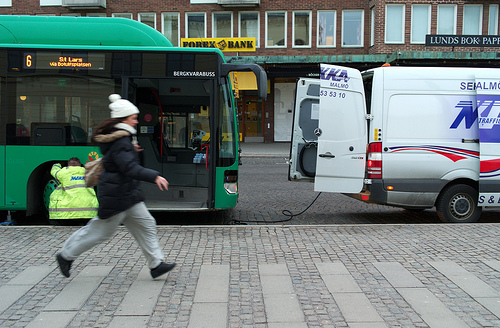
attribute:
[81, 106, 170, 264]
woman — running, walking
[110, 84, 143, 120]
hat — white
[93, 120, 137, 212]
jacket — black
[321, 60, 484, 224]
van — white, parked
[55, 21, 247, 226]
bus — green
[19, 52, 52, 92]
numbers — orange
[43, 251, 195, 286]
shoes — black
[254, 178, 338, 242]
cable — black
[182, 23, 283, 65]
sign — yellow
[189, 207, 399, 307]
sidewalk — concrete, brick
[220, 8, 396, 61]
windows — second story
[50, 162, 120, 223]
coat — yellow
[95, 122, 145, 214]
coat — black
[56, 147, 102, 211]
man — looking